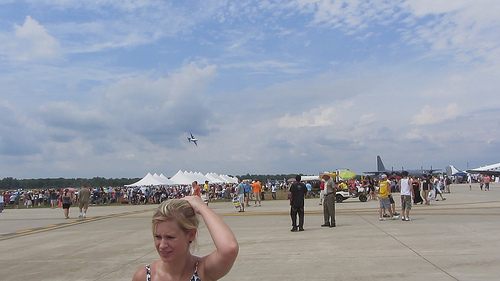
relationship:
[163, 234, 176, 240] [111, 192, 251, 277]
eye on woman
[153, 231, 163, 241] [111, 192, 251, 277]
eye on woman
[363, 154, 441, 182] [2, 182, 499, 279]
parked airplane on ground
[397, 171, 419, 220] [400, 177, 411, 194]
man in shirt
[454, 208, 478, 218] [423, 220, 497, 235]
line in concrete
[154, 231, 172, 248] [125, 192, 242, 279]
nose of person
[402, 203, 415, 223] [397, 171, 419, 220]
leg of man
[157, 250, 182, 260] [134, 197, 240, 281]
chin of person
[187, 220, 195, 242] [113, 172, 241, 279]
ears on woman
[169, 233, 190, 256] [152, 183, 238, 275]
cheek on woman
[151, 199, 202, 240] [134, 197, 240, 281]
blond hair on person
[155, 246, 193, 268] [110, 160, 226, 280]
neck on woman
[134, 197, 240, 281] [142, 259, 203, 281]
person wearing shirt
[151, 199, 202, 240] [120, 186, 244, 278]
blond hair on woman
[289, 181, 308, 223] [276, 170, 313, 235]
shirt on man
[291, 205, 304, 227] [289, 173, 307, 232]
black jeans on man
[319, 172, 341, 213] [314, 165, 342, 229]
cowboy hat on man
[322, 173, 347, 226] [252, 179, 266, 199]
man wearing shirt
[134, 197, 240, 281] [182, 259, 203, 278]
person wearing shirt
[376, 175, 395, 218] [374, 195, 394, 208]
man wearing shorts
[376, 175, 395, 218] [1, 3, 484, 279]
man watching an air show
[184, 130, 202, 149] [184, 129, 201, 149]
airplane flying in blue sky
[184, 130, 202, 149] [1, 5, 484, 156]
airplane flying in sky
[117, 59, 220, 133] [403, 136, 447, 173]
clouds hovering above ground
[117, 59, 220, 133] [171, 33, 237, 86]
clouds floating in sky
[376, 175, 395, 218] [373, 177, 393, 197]
man wearing a shirt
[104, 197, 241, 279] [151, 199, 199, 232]
person holding her blond hair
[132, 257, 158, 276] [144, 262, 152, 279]
shoulder supporting blouse strap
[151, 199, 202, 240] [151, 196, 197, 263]
blond hair attached to head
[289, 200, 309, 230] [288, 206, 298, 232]
pants covering leg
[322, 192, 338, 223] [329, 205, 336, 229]
pants covering leg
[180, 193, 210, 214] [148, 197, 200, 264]
hand holding head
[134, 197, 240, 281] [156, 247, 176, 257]
person squinching her mouth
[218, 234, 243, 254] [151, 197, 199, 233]
elbow bent holding hair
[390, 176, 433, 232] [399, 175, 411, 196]
man wearing a tank top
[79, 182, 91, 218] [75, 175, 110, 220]
man wearing khaki outfit